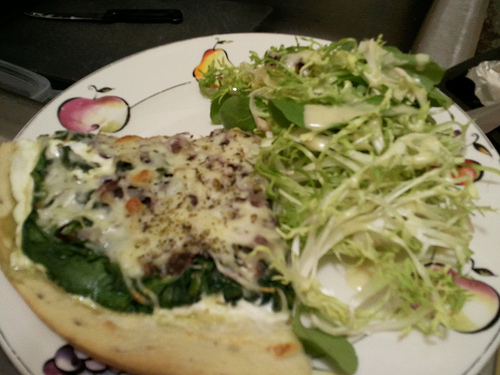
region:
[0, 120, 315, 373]
Pizza on a plate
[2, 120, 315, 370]
Pizza is on a plate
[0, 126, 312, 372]
Pizza on a white plate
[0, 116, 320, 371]
Pizza is on a white plate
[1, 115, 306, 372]
Pizza on a round plate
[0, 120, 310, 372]
Pizza is on a round plate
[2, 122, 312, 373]
Pizza on a round white plate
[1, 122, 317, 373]
Pizza is on a round white plate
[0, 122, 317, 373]
Slice of pizza on a plate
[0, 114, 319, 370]
Slice of pizza on a white plate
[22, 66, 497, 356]
A white plate with fruit design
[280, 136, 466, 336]
Vegetable sprouts on the plate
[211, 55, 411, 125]
Spinach salad on white plate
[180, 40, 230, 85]
A yellow pear on white plate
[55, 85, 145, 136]
A reddish apple design on a plate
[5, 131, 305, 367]
A slice of pizza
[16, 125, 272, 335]
A slice of pizza with spinach on it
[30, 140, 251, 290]
Slice of pizza with cheese on it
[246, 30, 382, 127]
A creamy dressing on salad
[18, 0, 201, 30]
A knife with black handle in background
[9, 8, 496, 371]
plate of food on a table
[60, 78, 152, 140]
image of apple on plate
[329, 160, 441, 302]
sprouts on a plate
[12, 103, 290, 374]
slice of vegetarian pizza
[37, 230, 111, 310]
spinach on a pizza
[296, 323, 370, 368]
green bean on a plate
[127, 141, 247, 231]
melted cheese on a pizza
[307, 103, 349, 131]
dressing on a bean sprout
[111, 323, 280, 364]
crust of a pizza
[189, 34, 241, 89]
image of a pear on plate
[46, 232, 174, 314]
green spinach on top of pizza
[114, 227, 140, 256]
yellow colored cheese on pizza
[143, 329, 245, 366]
light colored brown crust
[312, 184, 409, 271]
wild green salad on plate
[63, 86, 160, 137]
painted red and green apple on plate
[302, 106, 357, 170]
yellow dressing on top of salad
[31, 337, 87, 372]
purple grapes on plate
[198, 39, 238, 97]
yellow golden pear on plate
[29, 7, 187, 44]
dark handled knife in background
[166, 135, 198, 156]
brown chunks of meat on pizza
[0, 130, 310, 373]
Pizza on the plate.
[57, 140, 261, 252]
Melted cheese on the pizza.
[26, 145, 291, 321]
Green leafy vegetable on the pizza.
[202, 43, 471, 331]
Salad on the plate.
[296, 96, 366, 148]
White sauce on the salad.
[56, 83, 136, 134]
Apple design on the plate.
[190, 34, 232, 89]
Pear design on the plate.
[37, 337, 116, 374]
Grape image on the plate.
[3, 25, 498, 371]
White plate in the forefront.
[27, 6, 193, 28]
Knife on the plate.